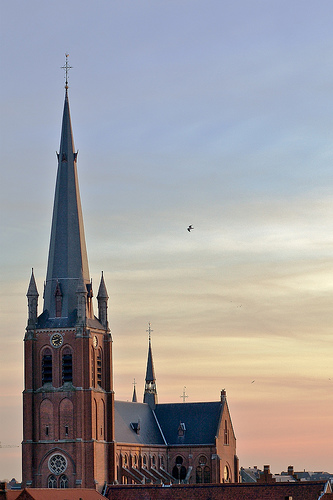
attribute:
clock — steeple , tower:
[47, 332, 64, 348]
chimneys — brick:
[255, 466, 305, 484]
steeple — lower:
[143, 341, 158, 403]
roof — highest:
[22, 87, 111, 330]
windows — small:
[31, 403, 90, 443]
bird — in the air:
[187, 222, 194, 235]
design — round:
[49, 282, 66, 317]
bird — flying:
[174, 209, 206, 240]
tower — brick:
[19, 49, 113, 334]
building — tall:
[15, 45, 120, 495]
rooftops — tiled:
[135, 368, 219, 452]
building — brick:
[2, 52, 329, 499]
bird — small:
[186, 223, 192, 232]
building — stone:
[4, 48, 247, 498]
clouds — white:
[1, 1, 332, 482]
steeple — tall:
[23, 53, 106, 323]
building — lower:
[114, 321, 240, 482]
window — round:
[48, 453, 67, 472]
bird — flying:
[186, 222, 195, 232]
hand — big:
[52, 337, 56, 342]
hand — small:
[56, 335, 59, 342]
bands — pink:
[2, 351, 326, 470]